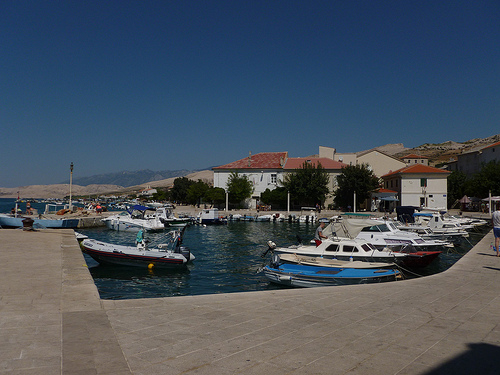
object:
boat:
[273, 235, 441, 267]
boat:
[310, 218, 455, 251]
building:
[283, 157, 351, 209]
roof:
[285, 157, 352, 171]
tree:
[277, 159, 332, 209]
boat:
[300, 214, 319, 223]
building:
[379, 163, 454, 215]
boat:
[384, 211, 472, 231]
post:
[68, 162, 74, 210]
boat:
[0, 213, 79, 227]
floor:
[0, 227, 498, 374]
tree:
[332, 159, 384, 212]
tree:
[260, 186, 273, 207]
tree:
[226, 171, 256, 210]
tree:
[203, 185, 227, 209]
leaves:
[345, 173, 372, 190]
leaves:
[294, 175, 320, 189]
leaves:
[233, 184, 245, 197]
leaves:
[186, 185, 199, 199]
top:
[296, 237, 399, 255]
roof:
[370, 187, 397, 193]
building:
[210, 151, 288, 209]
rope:
[393, 262, 420, 276]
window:
[270, 173, 278, 184]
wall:
[214, 170, 280, 195]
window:
[419, 177, 428, 188]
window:
[418, 197, 426, 206]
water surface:
[0, 198, 55, 210]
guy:
[313, 221, 327, 248]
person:
[95, 204, 103, 216]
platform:
[0, 228, 135, 373]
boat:
[80, 228, 196, 268]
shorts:
[492, 227, 499, 237]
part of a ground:
[139, 324, 183, 368]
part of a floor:
[15, 240, 60, 299]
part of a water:
[164, 267, 234, 288]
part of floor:
[62, 332, 101, 368]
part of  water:
[212, 218, 256, 254]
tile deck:
[0, 227, 500, 374]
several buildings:
[369, 153, 454, 214]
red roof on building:
[208, 152, 288, 169]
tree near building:
[456, 143, 499, 179]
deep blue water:
[76, 223, 314, 300]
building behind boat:
[366, 186, 397, 211]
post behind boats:
[224, 186, 229, 217]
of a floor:
[278, 325, 357, 369]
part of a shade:
[462, 359, 494, 373]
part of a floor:
[224, 299, 260, 358]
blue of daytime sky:
[0, 0, 499, 185]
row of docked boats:
[262, 207, 489, 287]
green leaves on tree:
[309, 185, 325, 199]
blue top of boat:
[264, 260, 399, 278]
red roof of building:
[400, 163, 452, 174]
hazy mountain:
[63, 168, 197, 186]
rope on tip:
[145, 229, 182, 250]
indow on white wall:
[419, 177, 427, 188]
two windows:
[407, 159, 418, 164]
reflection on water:
[273, 220, 314, 242]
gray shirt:
[313, 226, 324, 239]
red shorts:
[315, 239, 323, 247]